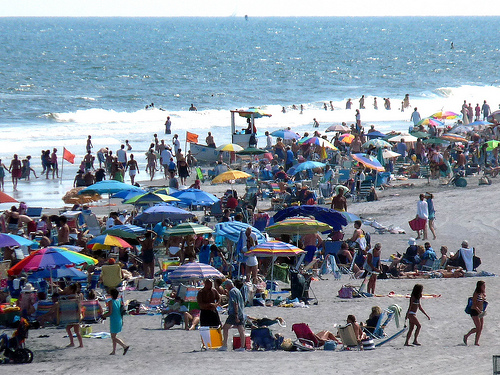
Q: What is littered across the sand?
A: People.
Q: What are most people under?
A: Umbrella.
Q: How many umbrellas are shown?
A: Thirty seven.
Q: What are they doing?
A: Sunbathing.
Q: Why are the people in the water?
A: Swimming.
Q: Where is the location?
A: Beach.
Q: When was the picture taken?
A: Day time.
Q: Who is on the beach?
A: Tourist.